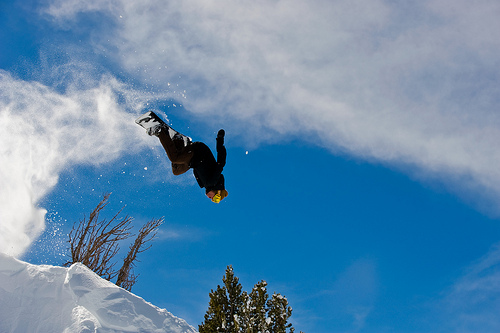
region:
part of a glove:
[211, 112, 226, 136]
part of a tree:
[236, 299, 262, 314]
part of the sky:
[272, 176, 330, 228]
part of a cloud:
[330, 85, 388, 153]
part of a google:
[199, 170, 228, 208]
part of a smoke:
[256, 6, 359, 153]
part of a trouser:
[158, 137, 192, 164]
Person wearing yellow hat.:
[207, 185, 227, 209]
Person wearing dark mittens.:
[213, 127, 225, 138]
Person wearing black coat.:
[196, 148, 228, 178]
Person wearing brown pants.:
[159, 152, 193, 187]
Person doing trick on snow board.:
[128, 119, 215, 183]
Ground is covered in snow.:
[51, 271, 123, 326]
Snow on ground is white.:
[36, 260, 91, 310]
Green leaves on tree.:
[217, 248, 266, 330]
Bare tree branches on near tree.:
[71, 222, 176, 285]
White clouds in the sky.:
[250, 49, 362, 116]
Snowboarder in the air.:
[141, 116, 230, 203]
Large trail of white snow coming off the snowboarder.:
[0, 67, 140, 264]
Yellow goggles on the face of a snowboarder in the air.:
[211, 187, 223, 203]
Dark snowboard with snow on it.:
[132, 112, 192, 148]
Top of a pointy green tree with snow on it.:
[197, 257, 299, 332]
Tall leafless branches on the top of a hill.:
[61, 195, 165, 295]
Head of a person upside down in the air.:
[202, 184, 227, 202]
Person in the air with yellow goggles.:
[147, 117, 230, 201]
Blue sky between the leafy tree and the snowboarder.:
[198, 210, 284, 266]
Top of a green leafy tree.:
[195, 265, 292, 332]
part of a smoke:
[282, 76, 341, 148]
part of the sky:
[300, 253, 352, 315]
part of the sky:
[303, 237, 380, 321]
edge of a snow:
[418, 155, 456, 180]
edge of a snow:
[133, 294, 164, 314]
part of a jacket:
[197, 160, 217, 178]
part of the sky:
[301, 152, 346, 199]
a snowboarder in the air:
[113, 91, 256, 216]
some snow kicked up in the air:
[0, 50, 206, 270]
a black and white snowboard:
[120, 95, 190, 145]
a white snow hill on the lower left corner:
[2, 235, 212, 330]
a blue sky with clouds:
[6, 6, 478, 326]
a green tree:
[188, 263, 304, 328]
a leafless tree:
[56, 186, 169, 302]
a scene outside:
[26, 13, 416, 329]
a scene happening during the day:
[17, 2, 432, 327]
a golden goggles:
[203, 180, 226, 208]